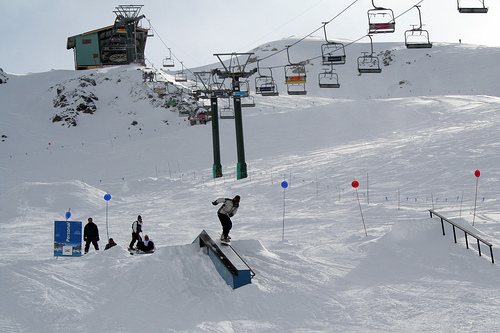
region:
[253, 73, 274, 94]
the metal ski lift chair above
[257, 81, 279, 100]
the metal ski lift chair above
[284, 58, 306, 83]
the metal ski lift chair above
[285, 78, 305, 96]
the metal ski lift chair above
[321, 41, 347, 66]
the metal ski lift chair above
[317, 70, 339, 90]
the metal ski lift chair above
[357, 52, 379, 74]
the metal ski lift chair above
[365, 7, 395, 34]
the metal ski lift chair above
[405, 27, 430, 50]
the metal ski lift chair above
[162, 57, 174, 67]
the metal ski lift chair above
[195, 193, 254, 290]
Snowboarder on a ramp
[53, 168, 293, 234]
Three poles in the snow with blue circles on top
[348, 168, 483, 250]
Two poles topped with red circles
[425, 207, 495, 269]
Small section of fence on the right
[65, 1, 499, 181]
Ski lift with colorful seats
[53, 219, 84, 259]
Large blue sign in the snow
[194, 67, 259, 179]
Large green metal poles holding up the ski lift wires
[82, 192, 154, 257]
People watching a snowboarder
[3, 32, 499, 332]
Hillside covered in snow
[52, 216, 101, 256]
Person in dark clothing standing next to a sign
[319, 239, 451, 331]
a ground covered in snow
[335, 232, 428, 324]
ground covered in white snow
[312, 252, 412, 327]
snow covering the ground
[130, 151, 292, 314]
a pers snowboarding outside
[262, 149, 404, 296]
sticks in the ground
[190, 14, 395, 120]
ski lift over the snow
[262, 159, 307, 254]
blue sticks in the snow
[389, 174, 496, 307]
a rail in the snow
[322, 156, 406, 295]
a red stick in the ground